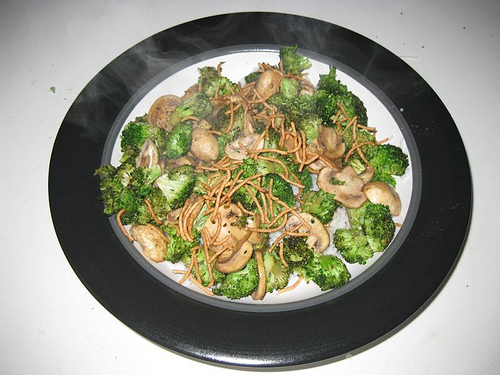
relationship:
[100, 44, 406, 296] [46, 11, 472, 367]
broccoli on dish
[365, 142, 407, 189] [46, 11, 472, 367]
broccoli on dish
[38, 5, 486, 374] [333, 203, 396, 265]
dish of vegetables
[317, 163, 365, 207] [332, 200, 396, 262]
mushroom and broccoli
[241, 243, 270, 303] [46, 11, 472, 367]
mushroom on dish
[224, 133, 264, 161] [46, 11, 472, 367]
mushroom on dish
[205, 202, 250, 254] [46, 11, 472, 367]
mushroom on dish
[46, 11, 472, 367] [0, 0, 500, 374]
dish on table